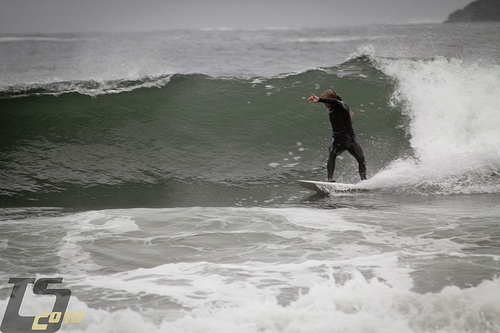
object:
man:
[306, 89, 367, 183]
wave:
[426, 132, 499, 163]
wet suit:
[318, 94, 367, 182]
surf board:
[297, 179, 361, 193]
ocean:
[0, 2, 499, 333]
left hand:
[306, 93, 319, 103]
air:
[190, 66, 323, 149]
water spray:
[406, 58, 499, 88]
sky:
[0, 1, 458, 27]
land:
[443, 0, 499, 25]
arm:
[318, 97, 344, 108]